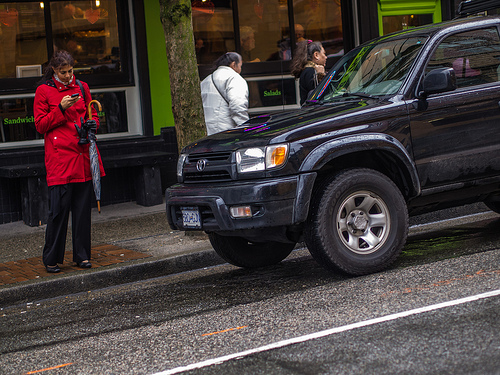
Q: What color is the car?
A: Black.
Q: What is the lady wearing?
A: Clothes.